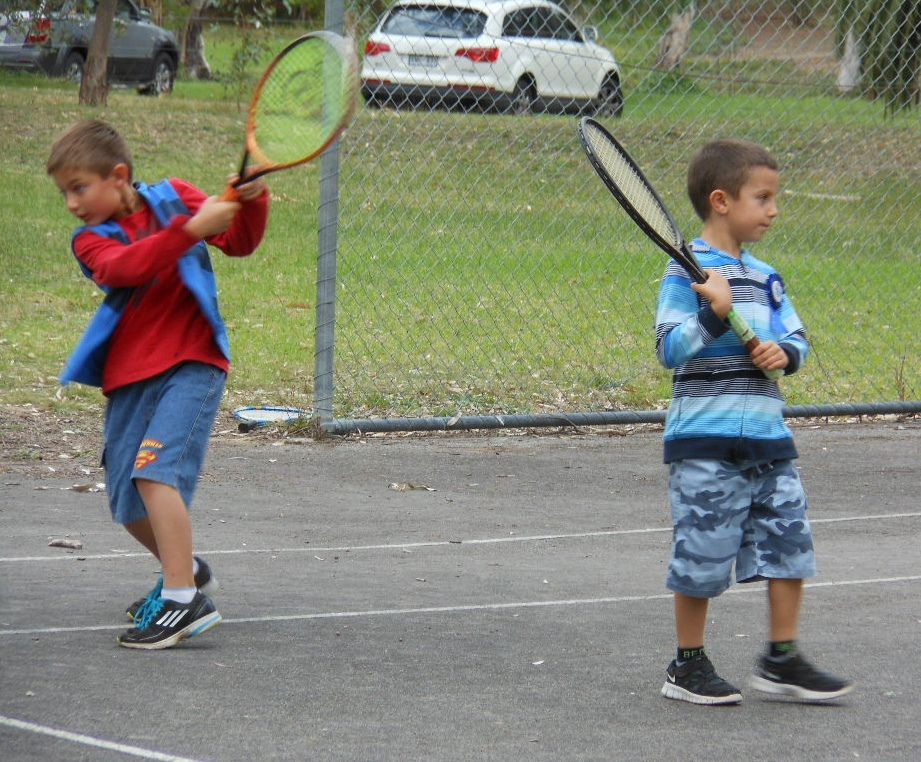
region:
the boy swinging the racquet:
[44, 116, 271, 655]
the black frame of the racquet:
[577, 112, 783, 381]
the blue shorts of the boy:
[665, 457, 820, 604]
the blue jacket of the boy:
[649, 237, 812, 465]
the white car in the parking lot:
[360, 4, 628, 127]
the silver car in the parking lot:
[1, 0, 187, 102]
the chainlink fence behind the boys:
[315, 3, 920, 435]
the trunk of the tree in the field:
[78, 0, 122, 109]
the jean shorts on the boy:
[103, 362, 227, 527]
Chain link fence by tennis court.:
[311, 0, 917, 436]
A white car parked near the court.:
[357, 0, 618, 111]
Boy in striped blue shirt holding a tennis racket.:
[572, 105, 850, 703]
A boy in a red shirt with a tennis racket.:
[43, 26, 364, 647]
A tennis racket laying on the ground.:
[230, 398, 310, 429]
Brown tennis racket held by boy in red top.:
[210, 26, 357, 199]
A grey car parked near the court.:
[0, 0, 181, 96]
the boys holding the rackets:
[43, 32, 853, 708]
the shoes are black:
[660, 654, 853, 706]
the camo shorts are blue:
[664, 442, 815, 597]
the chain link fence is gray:
[311, 0, 918, 442]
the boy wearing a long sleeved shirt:
[47, 116, 273, 651]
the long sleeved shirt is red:
[71, 176, 270, 398]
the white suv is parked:
[357, 0, 620, 117]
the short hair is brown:
[688, 137, 778, 222]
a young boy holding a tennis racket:
[580, 93, 785, 374]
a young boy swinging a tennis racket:
[51, 18, 361, 335]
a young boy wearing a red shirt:
[90, 181, 212, 394]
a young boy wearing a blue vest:
[83, 185, 206, 390]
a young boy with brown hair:
[685, 142, 778, 209]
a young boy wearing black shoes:
[648, 652, 863, 707]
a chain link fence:
[392, 12, 918, 423]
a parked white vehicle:
[344, 0, 630, 109]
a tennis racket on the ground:
[230, 397, 312, 439]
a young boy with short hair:
[50, 113, 143, 184]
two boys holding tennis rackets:
[43, 23, 845, 700]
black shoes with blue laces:
[110, 548, 216, 646]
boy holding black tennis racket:
[572, 102, 849, 703]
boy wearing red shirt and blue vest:
[44, 116, 267, 648]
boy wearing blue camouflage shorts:
[647, 110, 853, 707]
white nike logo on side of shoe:
[664, 667, 681, 684]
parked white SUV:
[355, 0, 624, 115]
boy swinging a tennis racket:
[44, 28, 365, 652]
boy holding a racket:
[548, 82, 882, 710]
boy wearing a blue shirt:
[555, 88, 914, 705]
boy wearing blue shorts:
[521, 101, 895, 714]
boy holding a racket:
[49, 0, 356, 668]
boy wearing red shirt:
[24, 36, 370, 662]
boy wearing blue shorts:
[28, 32, 374, 722]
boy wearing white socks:
[74, 28, 366, 667]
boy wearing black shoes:
[74, 28, 408, 712]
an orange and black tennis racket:
[192, 34, 368, 260]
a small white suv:
[361, 0, 643, 114]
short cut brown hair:
[36, 114, 141, 195]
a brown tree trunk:
[80, 0, 124, 105]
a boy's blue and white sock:
[160, 580, 212, 601]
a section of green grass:
[360, 157, 629, 405]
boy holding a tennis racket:
[540, 101, 876, 706]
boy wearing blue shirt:
[578, 68, 881, 732]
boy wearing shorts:
[585, 93, 896, 716]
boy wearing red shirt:
[28, 30, 367, 672]